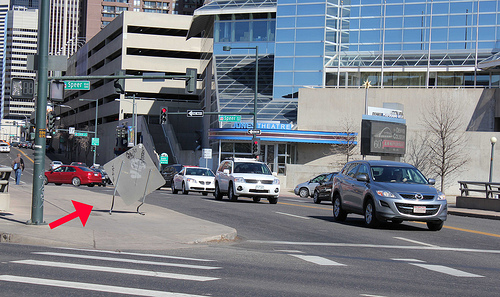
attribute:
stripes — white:
[1, 243, 238, 294]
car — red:
[44, 156, 108, 192]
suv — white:
[213, 157, 280, 203]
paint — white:
[292, 252, 341, 269]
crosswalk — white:
[15, 249, 191, 294]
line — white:
[289, 252, 348, 274]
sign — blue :
[240, 122, 271, 136]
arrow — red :
[26, 184, 96, 261]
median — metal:
[450, 170, 499, 201]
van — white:
[207, 150, 286, 207]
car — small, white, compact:
[286, 130, 462, 229]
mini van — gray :
[330, 160, 445, 226]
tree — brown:
[421, 96, 468, 195]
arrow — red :
[49, 199, 92, 230]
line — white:
[3, 248, 200, 291]